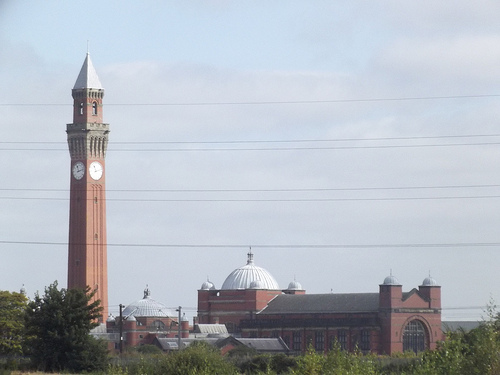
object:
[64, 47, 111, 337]
tower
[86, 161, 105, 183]
clock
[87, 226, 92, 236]
brick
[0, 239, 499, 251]
powerlines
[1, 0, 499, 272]
sky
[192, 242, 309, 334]
building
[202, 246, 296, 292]
white dome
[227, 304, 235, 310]
brick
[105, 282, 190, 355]
building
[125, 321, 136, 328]
brick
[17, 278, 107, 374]
trees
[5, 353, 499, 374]
ground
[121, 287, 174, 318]
white dome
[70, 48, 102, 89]
point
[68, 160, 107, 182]
two clocks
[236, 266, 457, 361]
building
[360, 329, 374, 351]
windows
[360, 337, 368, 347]
bars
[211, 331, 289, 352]
roof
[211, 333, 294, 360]
building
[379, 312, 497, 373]
bushes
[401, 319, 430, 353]
window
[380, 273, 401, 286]
small domes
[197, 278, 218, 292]
small domes